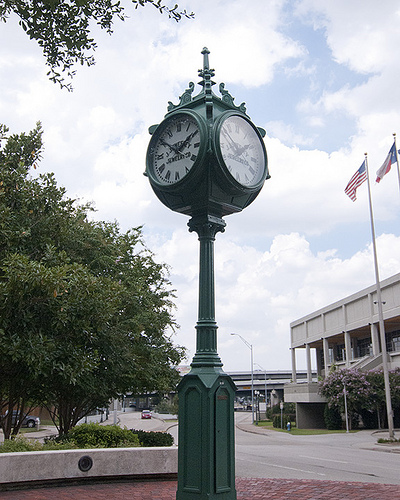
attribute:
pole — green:
[184, 340, 267, 487]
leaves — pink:
[322, 366, 375, 412]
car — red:
[140, 410, 154, 421]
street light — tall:
[227, 330, 266, 426]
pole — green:
[178, 214, 240, 499]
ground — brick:
[5, 478, 399, 498]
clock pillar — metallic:
[171, 214, 249, 499]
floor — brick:
[0, 474, 397, 498]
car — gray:
[5, 410, 41, 434]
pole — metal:
[141, 45, 271, 498]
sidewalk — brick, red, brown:
[1, 476, 398, 498]